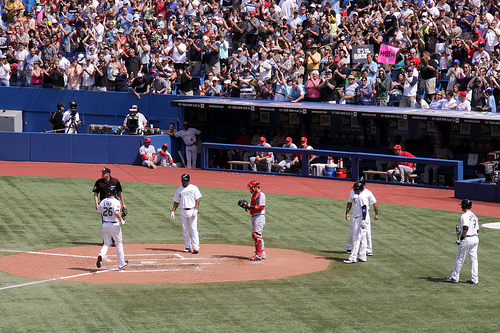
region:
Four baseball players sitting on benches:
[228, 137, 416, 181]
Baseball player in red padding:
[239, 179, 266, 261]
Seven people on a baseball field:
[90, 165, 482, 290]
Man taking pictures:
[60, 98, 82, 133]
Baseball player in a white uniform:
[446, 198, 482, 286]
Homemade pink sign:
[375, 42, 400, 65]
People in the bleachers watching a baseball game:
[0, 0, 499, 115]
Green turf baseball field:
[0, 158, 498, 332]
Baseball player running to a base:
[93, 182, 130, 269]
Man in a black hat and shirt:
[91, 165, 125, 219]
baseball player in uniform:
[91, 180, 133, 267]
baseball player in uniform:
[168, 169, 216, 247]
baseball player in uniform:
[248, 184, 276, 259]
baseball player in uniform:
[322, 182, 380, 255]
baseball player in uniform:
[429, 196, 479, 271]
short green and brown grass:
[14, 175, 49, 208]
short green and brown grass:
[268, 293, 293, 314]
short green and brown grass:
[336, 300, 393, 328]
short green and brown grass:
[66, 305, 119, 330]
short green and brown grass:
[147, 293, 198, 328]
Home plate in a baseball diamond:
[142, 260, 156, 265]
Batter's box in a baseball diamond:
[104, 253, 203, 270]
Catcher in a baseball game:
[238, 177, 267, 260]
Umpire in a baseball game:
[90, 165, 127, 216]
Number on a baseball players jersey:
[102, 206, 114, 216]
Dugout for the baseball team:
[170, 96, 499, 195]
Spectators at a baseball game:
[0, 2, 498, 112]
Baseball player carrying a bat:
[450, 198, 479, 283]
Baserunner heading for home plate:
[96, 184, 128, 270]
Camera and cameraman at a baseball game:
[125, 104, 146, 136]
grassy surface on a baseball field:
[0, 173, 499, 332]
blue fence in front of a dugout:
[200, 141, 465, 191]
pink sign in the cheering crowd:
[376, 41, 401, 65]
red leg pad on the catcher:
[252, 233, 264, 256]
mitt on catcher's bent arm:
[238, 199, 248, 210]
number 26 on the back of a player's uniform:
[101, 206, 116, 218]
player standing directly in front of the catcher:
[168, 173, 205, 253]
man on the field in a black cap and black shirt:
[91, 167, 129, 213]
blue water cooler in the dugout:
[324, 156, 339, 179]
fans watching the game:
[0, 0, 499, 110]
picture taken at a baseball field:
[4, 12, 492, 323]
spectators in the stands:
[49, 10, 494, 80]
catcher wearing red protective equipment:
[225, 174, 282, 269]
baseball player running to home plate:
[82, 181, 134, 283]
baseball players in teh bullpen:
[236, 124, 458, 184]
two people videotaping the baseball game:
[62, 100, 156, 132]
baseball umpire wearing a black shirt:
[90, 160, 133, 245]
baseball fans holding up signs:
[341, 35, 411, 72]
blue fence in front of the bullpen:
[201, 149, 466, 184]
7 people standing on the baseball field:
[46, 168, 495, 292]